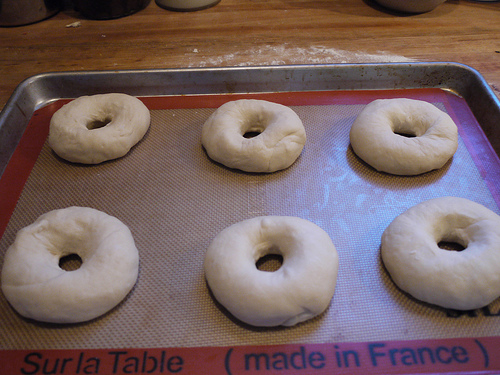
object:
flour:
[186, 43, 418, 68]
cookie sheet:
[0, 62, 500, 372]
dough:
[2, 205, 139, 324]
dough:
[49, 94, 150, 165]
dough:
[204, 216, 338, 325]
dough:
[203, 100, 308, 174]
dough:
[351, 98, 458, 175]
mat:
[0, 90, 499, 374]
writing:
[22, 339, 490, 374]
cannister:
[0, 1, 50, 27]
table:
[0, 1, 500, 115]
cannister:
[364, 2, 444, 14]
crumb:
[65, 20, 83, 29]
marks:
[495, 49, 500, 54]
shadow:
[354, 2, 458, 18]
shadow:
[179, 119, 284, 182]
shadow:
[347, 141, 455, 189]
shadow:
[378, 241, 470, 318]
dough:
[380, 198, 499, 312]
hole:
[87, 115, 112, 131]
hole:
[244, 126, 263, 138]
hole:
[393, 127, 419, 139]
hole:
[58, 251, 83, 272]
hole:
[256, 251, 284, 272]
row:
[48, 93, 458, 176]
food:
[5, 93, 499, 326]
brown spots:
[385, 66, 471, 92]